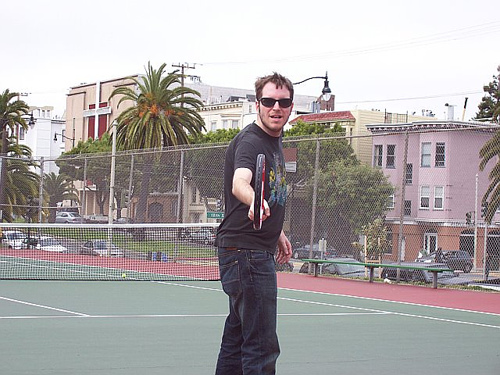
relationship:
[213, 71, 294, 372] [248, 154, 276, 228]
man has racket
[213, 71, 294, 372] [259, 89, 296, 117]
man in sunglasses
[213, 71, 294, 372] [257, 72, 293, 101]
man has hair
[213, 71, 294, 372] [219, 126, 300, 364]
man in black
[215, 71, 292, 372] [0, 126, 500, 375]
man on court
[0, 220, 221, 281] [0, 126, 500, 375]
net on court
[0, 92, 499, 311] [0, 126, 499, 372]
fence surrounding court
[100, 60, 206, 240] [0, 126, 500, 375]
palm tree outside court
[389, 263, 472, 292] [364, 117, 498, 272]
truck parked next to building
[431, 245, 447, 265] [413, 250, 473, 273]
person getting in car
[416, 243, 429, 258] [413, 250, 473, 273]
person getting in car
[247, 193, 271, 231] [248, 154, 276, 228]
hand holding racket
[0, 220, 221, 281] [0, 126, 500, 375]
net stretched across court